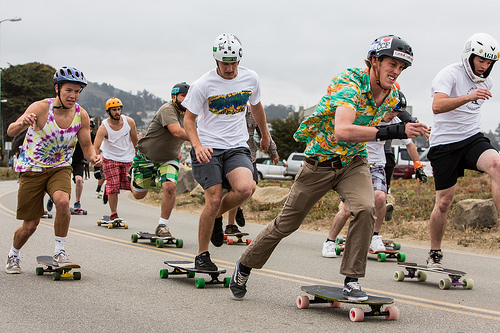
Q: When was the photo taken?
A: Daytime.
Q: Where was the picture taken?
A: On the street.